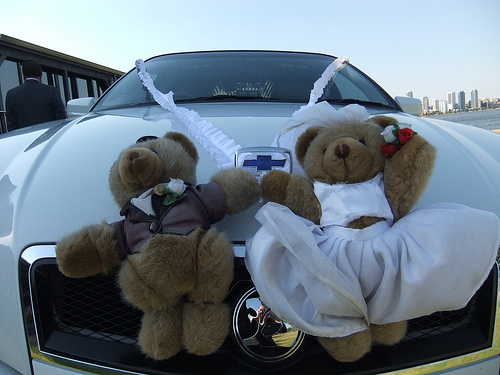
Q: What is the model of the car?
A: Chevy.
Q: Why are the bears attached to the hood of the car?
A: Decoration.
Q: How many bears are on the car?
A: 2.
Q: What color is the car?
A: White.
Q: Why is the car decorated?
A: Wedding.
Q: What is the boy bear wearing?
A: Tuxedo.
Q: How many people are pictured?
A: 0.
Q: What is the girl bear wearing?
A: Dress.